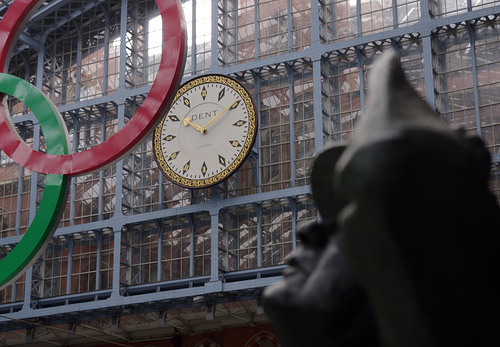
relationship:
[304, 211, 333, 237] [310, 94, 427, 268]
nose on statue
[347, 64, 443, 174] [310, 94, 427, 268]
elbow of statue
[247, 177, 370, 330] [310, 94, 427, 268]
face on statue